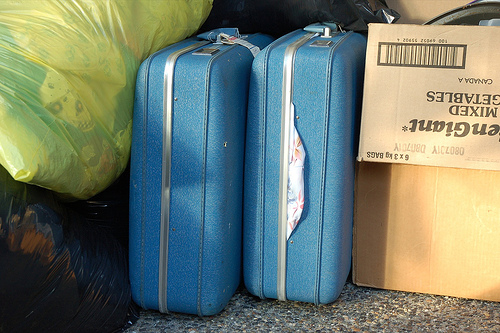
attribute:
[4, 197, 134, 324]
plastic bag — black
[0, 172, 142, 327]
plastic bag — black, full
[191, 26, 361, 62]
handles — blue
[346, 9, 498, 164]
box — cardboard, stacked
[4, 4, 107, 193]
bag — plastic, yellow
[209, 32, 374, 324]
suitcase — blue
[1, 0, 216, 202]
bags — plastic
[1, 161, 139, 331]
bags — plastic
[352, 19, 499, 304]
box — cardboard, brown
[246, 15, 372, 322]
luggage — light, blue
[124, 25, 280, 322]
luggage — light, blue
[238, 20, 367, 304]
luggage — blue, light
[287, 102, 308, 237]
item — white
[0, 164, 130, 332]
bag — plastic, black